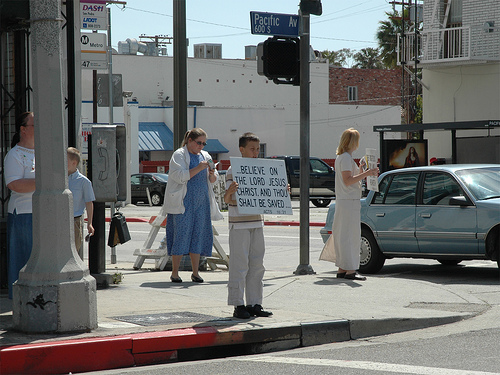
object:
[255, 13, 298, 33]
letters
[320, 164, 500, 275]
sedan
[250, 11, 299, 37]
sign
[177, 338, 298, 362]
drain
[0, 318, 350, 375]
curb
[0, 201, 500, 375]
sidewalk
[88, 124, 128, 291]
payphone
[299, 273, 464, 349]
street corner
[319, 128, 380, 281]
woman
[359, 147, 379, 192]
sign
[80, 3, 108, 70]
metro sign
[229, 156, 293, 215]
sign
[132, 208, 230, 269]
barrier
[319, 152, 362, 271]
dress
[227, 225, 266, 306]
pants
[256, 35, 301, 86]
signal box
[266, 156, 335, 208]
truck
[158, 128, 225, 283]
woman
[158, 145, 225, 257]
dress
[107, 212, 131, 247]
phone book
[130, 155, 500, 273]
background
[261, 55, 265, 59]
av.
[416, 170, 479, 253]
door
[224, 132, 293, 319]
boy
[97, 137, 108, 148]
coin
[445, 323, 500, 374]
corner